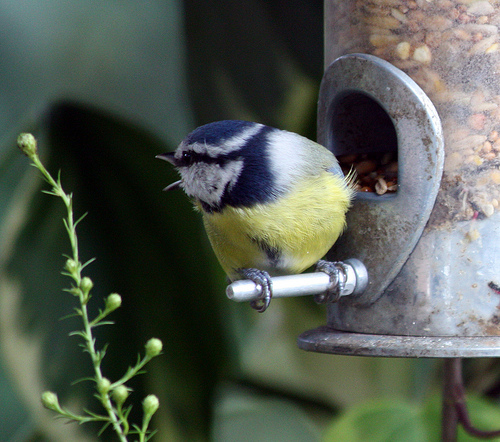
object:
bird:
[154, 118, 360, 314]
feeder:
[224, 1, 498, 360]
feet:
[236, 265, 274, 314]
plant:
[14, 128, 164, 441]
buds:
[102, 290, 124, 314]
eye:
[183, 151, 191, 161]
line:
[190, 150, 242, 168]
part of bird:
[186, 183, 359, 283]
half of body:
[152, 118, 360, 210]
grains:
[390, 39, 411, 63]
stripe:
[188, 121, 266, 156]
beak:
[153, 153, 185, 193]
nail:
[325, 273, 341, 291]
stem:
[30, 152, 131, 441]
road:
[223, 255, 368, 306]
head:
[173, 119, 249, 197]